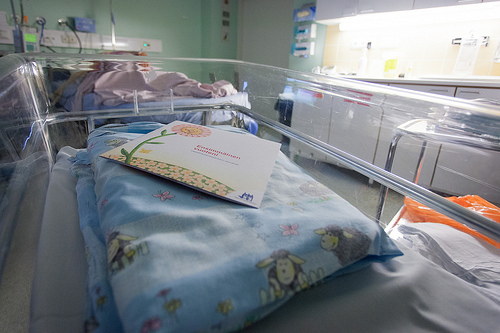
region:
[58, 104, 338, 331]
blue blanket in baby bed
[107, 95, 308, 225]
white envelope on blanket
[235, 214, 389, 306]
sheep on the blanket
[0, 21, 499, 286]
baby bed made of plastic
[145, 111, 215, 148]
pink flower on envelope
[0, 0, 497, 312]
scene takes place in hospital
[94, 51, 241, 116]
pink blanket on bed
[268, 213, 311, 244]
pink butterfly on blanket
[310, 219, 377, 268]
the sheep is black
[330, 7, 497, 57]
lights turned on under cabinet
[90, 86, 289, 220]
a white card on a blanket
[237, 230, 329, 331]
an animal on a blue blanket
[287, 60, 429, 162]
white cabinets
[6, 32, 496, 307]
clear bassinet for a baby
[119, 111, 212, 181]
a flower on a white card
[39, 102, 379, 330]
blue baby blanket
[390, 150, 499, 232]
orange garbage bag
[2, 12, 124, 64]
medical supplies on the wall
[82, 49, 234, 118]
pink blanket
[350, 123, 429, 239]
metal leg of a tray table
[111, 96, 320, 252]
white card with a flower on it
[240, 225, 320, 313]
a sheep on a baby blanket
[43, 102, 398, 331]
a blue baby blanket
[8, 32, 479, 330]
a clear bassinet for a baby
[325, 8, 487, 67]
bright white lights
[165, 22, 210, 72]
a green wall in the back of the room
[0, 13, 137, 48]
medical equipment on the wall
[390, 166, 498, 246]
an orange bag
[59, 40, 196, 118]
a pink blanket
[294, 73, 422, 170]
white cabinets on the wall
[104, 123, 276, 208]
Card with a yellow flower on it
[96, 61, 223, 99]
Pink blanket on a hospital bed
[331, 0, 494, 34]
Fluorescent lighting above counter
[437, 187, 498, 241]
Orange bag on cart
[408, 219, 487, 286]
White sheets on cart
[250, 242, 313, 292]
Brown cartoon sheep on bed sheet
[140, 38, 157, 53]
Green light above hospital bed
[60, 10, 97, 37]
Purple hospital equipment above light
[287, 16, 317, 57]
Exam gloves in boxes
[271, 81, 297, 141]
Black trash bin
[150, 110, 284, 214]
Pamphlet with a flower on the front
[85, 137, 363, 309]
A blanket with a sheep design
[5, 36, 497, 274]
A plastic baby incubator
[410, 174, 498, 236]
Orange plastic bag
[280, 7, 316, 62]
Three glove dispenser boxes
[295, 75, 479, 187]
Set of white cabinets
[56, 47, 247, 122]
A person lying in a hospital bed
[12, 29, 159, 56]
An electrical outlet strip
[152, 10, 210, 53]
Light green wall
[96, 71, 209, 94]
Pink hospital sheet